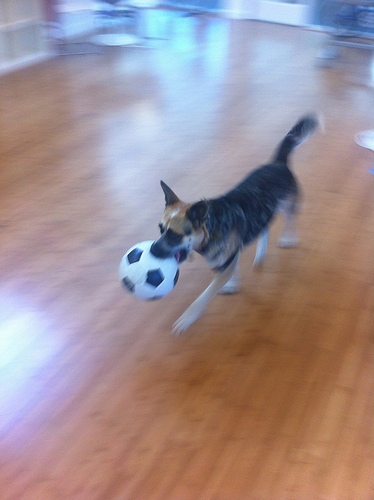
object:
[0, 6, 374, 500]
floor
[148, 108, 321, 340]
dog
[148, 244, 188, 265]
mouth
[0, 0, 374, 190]
background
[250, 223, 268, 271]
legs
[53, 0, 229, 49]
light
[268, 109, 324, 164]
tail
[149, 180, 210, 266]
head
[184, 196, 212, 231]
ears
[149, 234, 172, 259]
snout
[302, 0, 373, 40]
furniture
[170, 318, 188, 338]
front paw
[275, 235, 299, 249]
rear paw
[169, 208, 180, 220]
spot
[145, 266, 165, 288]
pentagons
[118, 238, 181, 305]
soccer ball